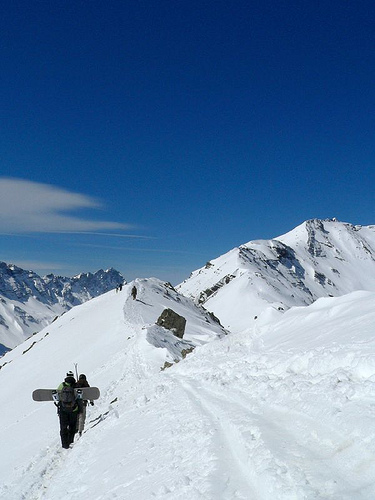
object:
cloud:
[2, 175, 163, 280]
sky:
[251, 2, 372, 175]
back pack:
[52, 380, 83, 415]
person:
[131, 286, 137, 300]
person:
[115, 283, 118, 294]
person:
[119, 283, 123, 291]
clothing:
[119, 284, 122, 289]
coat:
[130, 286, 137, 294]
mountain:
[173, 219, 373, 326]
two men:
[57, 370, 95, 447]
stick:
[73, 362, 79, 381]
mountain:
[0, 266, 126, 354]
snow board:
[32, 387, 101, 402]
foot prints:
[15, 441, 70, 498]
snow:
[302, 276, 375, 358]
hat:
[66, 370, 75, 377]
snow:
[211, 235, 292, 305]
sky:
[9, 8, 135, 136]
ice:
[110, 277, 146, 347]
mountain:
[85, 268, 220, 359]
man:
[56, 370, 82, 448]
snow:
[258, 456, 361, 500]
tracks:
[172, 369, 359, 498]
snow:
[1, 426, 26, 498]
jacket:
[56, 379, 83, 412]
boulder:
[155, 307, 187, 338]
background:
[1, 153, 373, 355]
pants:
[57, 409, 77, 446]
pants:
[133, 294, 136, 298]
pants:
[77, 400, 87, 435]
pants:
[116, 288, 118, 292]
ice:
[1, 384, 105, 499]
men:
[76, 374, 94, 436]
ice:
[286, 275, 374, 469]